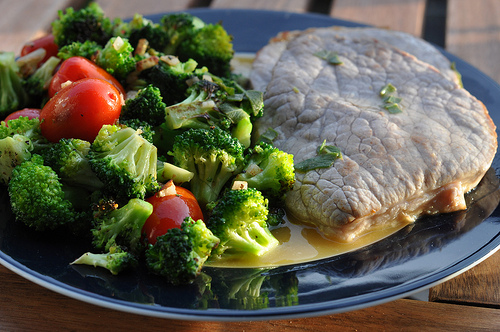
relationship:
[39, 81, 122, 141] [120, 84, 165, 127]
tomato next to broccoli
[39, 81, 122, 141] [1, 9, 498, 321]
tomato on top of plate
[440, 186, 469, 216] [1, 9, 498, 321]
meat on top of plate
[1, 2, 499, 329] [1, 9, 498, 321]
table under plate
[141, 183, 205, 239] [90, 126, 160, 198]
tomato under broccoli